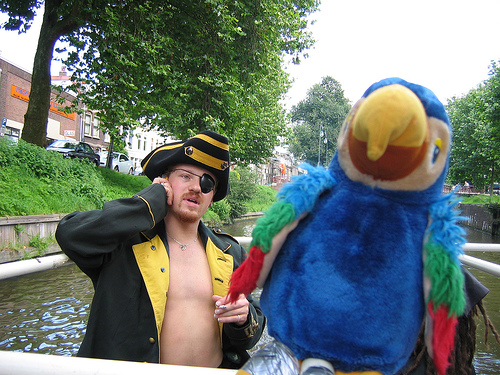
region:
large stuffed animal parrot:
[213, 70, 496, 372]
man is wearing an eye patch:
[149, 153, 226, 202]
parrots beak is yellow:
[358, 79, 425, 169]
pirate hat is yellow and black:
[135, 113, 257, 208]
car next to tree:
[18, 125, 115, 174]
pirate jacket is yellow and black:
[66, 172, 264, 373]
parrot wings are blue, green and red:
[242, 147, 467, 373]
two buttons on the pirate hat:
[182, 136, 233, 177]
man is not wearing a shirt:
[145, 222, 231, 368]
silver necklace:
[153, 227, 211, 256]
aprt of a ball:
[360, 240, 400, 297]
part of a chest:
[168, 262, 178, 293]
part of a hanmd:
[213, 287, 225, 309]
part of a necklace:
[163, 235, 181, 272]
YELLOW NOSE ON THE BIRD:
[360, 89, 424, 154]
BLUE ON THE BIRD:
[356, 201, 406, 282]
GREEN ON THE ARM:
[438, 259, 455, 289]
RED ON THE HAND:
[440, 324, 451, 365]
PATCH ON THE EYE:
[198, 175, 213, 186]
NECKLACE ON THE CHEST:
[178, 241, 193, 251]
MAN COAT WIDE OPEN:
[121, 245, 163, 328]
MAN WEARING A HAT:
[178, 137, 238, 162]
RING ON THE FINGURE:
[161, 183, 169, 187]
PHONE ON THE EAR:
[161, 177, 171, 189]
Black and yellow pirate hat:
[134, 130, 243, 177]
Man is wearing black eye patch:
[164, 168, 221, 225]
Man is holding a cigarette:
[211, 295, 241, 322]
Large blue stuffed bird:
[251, 75, 488, 370]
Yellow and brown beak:
[345, 81, 430, 183]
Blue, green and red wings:
[420, 199, 473, 371]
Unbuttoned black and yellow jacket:
[52, 186, 267, 364]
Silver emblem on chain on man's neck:
[163, 226, 203, 253]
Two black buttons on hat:
[180, 141, 236, 173]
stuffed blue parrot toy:
[256, 77, 461, 372]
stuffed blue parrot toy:
[247, 65, 447, 367]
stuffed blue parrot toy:
[269, 85, 460, 357]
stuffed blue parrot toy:
[255, 115, 460, 371]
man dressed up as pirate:
[97, 134, 264, 366]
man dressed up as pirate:
[82, 135, 259, 354]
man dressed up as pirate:
[83, 128, 266, 353]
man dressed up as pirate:
[81, 137, 251, 361]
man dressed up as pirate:
[87, 125, 260, 356]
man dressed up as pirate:
[102, 143, 268, 368]